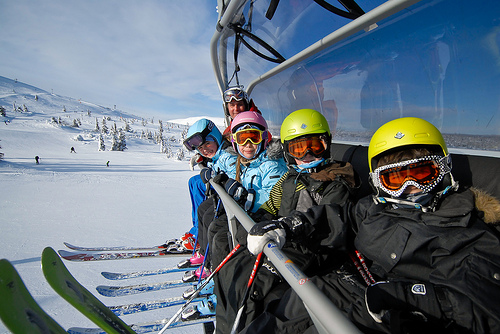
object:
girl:
[180, 117, 236, 252]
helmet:
[187, 117, 222, 156]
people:
[35, 156, 40, 165]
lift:
[206, 0, 499, 334]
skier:
[223, 85, 262, 142]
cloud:
[5, 4, 216, 110]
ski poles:
[58, 250, 175, 263]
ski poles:
[97, 280, 202, 298]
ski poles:
[107, 297, 203, 317]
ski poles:
[43, 246, 145, 333]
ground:
[34, 192, 127, 236]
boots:
[196, 276, 216, 298]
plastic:
[281, 249, 336, 332]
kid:
[222, 107, 360, 334]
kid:
[273, 116, 500, 333]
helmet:
[367, 117, 452, 196]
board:
[0, 259, 73, 334]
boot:
[196, 294, 217, 318]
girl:
[188, 111, 290, 279]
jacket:
[237, 140, 290, 218]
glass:
[369, 153, 453, 197]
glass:
[284, 133, 332, 161]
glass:
[232, 128, 267, 146]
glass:
[182, 132, 206, 151]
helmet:
[279, 109, 332, 165]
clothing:
[262, 187, 499, 334]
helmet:
[230, 111, 268, 154]